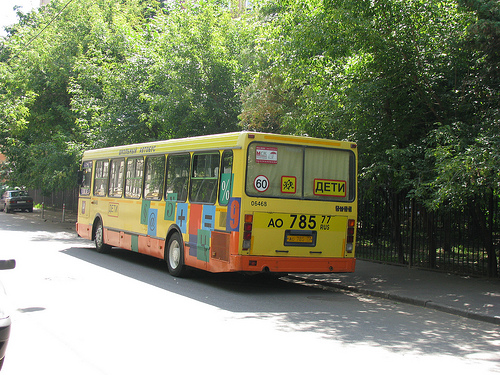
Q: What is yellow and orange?
A: Bus.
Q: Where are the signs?
A: On bus.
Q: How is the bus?
A: Stopped.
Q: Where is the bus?
A: Side of road.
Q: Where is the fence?
A: Along sidewalk.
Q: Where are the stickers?
A: On bus.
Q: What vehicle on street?
A: Bus.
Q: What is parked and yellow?
A: A bus.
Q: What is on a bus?
A: Colored signs.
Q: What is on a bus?
A: Colored signs.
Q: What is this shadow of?
A: A bus.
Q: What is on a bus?
A: Two tires.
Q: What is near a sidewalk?
A: A fence.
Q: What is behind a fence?
A: Trees.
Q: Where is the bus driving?
A: Street.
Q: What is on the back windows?
A: Curtains.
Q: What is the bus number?
A: Seven eight five.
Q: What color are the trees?
A: Green.